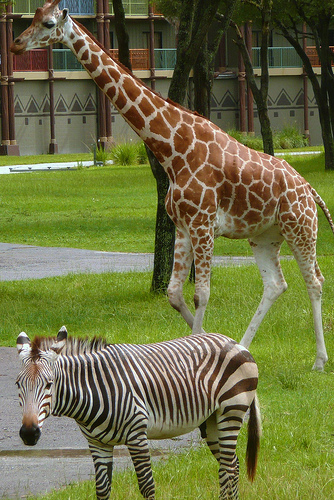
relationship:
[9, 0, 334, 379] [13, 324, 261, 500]
giraffe by zebra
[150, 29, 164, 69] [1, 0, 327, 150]
door on building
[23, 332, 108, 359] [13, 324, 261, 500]
mane on zebra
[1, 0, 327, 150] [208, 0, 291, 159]
building by tree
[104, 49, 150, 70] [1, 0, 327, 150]
railing on building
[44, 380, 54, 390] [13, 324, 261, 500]
eye on zebra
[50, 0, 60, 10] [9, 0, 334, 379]
horn on giraffe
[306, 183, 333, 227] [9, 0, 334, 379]
tail on giraffe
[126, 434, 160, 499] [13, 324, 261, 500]
leg on zebra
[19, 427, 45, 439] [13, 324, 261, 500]
nose on zebra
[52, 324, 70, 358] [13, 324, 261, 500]
ear on zebra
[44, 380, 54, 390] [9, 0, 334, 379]
eye on giraffe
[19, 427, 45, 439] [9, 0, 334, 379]
nose on giraffe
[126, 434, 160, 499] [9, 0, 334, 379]
leg on giraffe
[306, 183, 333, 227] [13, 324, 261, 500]
tail on zebra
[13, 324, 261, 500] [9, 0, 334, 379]
zebra by giraffe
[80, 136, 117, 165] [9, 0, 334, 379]
plant by giraffe